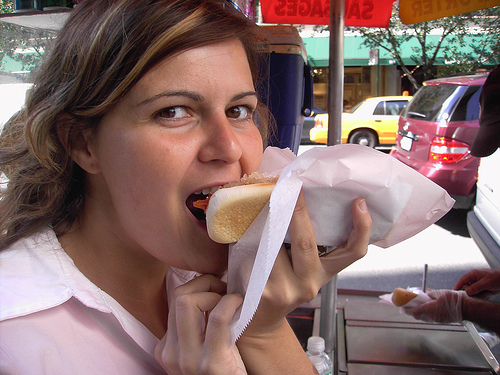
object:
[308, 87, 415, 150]
cab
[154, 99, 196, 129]
eye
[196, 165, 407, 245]
hotdog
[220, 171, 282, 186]
onion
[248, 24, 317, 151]
cooler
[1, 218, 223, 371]
shirt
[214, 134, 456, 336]
napkin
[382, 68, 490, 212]
van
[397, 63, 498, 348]
worker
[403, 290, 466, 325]
glove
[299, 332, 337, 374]
bottle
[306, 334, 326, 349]
top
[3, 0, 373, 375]
woman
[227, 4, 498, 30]
umbrella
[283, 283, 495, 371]
cart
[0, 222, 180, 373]
collar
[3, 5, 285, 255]
hair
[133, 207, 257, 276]
jaw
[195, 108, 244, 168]
nose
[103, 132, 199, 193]
cheek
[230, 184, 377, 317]
hand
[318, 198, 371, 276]
finger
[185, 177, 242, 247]
mouth